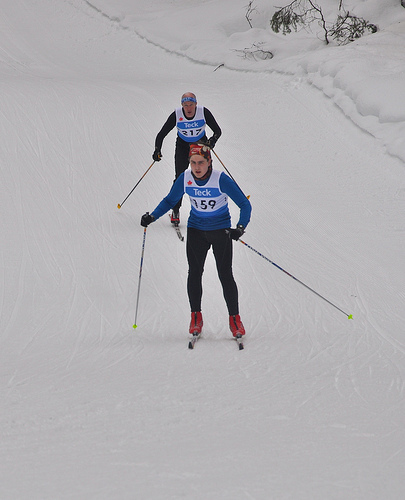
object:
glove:
[139, 213, 156, 226]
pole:
[132, 211, 151, 329]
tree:
[268, 0, 371, 44]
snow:
[0, 0, 405, 500]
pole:
[115, 154, 158, 210]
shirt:
[148, 171, 250, 232]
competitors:
[152, 89, 223, 224]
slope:
[0, 0, 405, 500]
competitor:
[141, 142, 252, 339]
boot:
[188, 308, 202, 334]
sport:
[139, 89, 252, 355]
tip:
[179, 334, 201, 354]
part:
[188, 313, 203, 329]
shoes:
[185, 312, 206, 338]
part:
[283, 30, 323, 93]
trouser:
[186, 229, 239, 312]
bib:
[188, 192, 227, 218]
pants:
[185, 228, 240, 316]